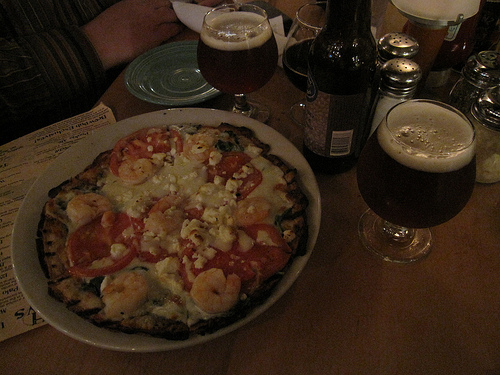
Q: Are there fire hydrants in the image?
A: No, there are no fire hydrants.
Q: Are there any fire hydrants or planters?
A: No, there are no fire hydrants or planters.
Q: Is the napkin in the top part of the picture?
A: Yes, the napkin is in the top of the image.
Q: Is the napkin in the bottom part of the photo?
A: No, the napkin is in the top of the image.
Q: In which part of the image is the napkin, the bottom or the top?
A: The napkin is in the top of the image.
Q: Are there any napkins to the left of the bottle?
A: Yes, there is a napkin to the left of the bottle.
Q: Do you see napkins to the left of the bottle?
A: Yes, there is a napkin to the left of the bottle.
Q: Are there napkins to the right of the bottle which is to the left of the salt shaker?
A: No, the napkin is to the left of the bottle.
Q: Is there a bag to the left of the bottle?
A: No, there is a napkin to the left of the bottle.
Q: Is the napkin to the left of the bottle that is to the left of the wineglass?
A: Yes, the napkin is to the left of the bottle.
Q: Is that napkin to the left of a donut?
A: No, the napkin is to the left of the bottle.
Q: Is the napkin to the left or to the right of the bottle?
A: The napkin is to the left of the bottle.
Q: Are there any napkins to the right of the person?
A: Yes, there is a napkin to the right of the person.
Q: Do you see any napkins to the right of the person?
A: Yes, there is a napkin to the right of the person.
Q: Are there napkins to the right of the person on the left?
A: Yes, there is a napkin to the right of the person.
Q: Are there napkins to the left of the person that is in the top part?
A: No, the napkin is to the right of the person.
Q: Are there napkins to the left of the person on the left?
A: No, the napkin is to the right of the person.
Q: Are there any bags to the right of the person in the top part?
A: No, there is a napkin to the right of the person.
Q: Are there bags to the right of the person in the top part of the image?
A: No, there is a napkin to the right of the person.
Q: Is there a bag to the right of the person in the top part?
A: No, there is a napkin to the right of the person.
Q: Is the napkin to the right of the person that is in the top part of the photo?
A: Yes, the napkin is to the right of the person.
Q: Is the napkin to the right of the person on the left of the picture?
A: Yes, the napkin is to the right of the person.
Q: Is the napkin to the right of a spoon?
A: No, the napkin is to the right of the person.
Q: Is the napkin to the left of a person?
A: No, the napkin is to the right of a person.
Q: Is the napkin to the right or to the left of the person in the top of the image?
A: The napkin is to the right of the person.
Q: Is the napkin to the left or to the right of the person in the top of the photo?
A: The napkin is to the right of the person.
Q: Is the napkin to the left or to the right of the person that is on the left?
A: The napkin is to the right of the person.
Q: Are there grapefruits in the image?
A: No, there are no grapefruits.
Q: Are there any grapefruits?
A: No, there are no grapefruits.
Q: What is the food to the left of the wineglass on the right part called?
A: The food is shrimp.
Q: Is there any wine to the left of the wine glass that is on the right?
A: No, there is shrimp to the left of the wine glass.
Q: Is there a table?
A: Yes, there is a table.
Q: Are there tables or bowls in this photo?
A: Yes, there is a table.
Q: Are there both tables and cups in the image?
A: No, there is a table but no cups.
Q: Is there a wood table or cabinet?
A: Yes, there is a wood table.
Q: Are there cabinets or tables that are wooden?
A: Yes, the table is wooden.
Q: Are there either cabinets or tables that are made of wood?
A: Yes, the table is made of wood.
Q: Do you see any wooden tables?
A: Yes, there is a wood table.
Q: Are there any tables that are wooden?
A: Yes, there is a table that is wooden.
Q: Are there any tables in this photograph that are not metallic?
A: Yes, there is a wooden table.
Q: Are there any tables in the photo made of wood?
A: Yes, there is a table that is made of wood.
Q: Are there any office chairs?
A: No, there are no office chairs.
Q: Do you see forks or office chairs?
A: No, there are no office chairs or forks.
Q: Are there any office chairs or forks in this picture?
A: No, there are no office chairs or forks.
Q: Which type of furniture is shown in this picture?
A: The furniture is a table.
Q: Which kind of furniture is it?
A: The piece of furniture is a table.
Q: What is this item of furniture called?
A: This is a table.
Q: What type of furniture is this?
A: This is a table.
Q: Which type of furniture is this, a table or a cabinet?
A: This is a table.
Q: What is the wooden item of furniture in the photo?
A: The piece of furniture is a table.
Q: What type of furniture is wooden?
A: The furniture is a table.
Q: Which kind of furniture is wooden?
A: The furniture is a table.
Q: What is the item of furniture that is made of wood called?
A: The piece of furniture is a table.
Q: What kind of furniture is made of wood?
A: The furniture is a table.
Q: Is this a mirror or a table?
A: This is a table.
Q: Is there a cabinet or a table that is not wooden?
A: No, there is a table but it is wooden.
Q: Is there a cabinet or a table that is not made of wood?
A: No, there is a table but it is made of wood.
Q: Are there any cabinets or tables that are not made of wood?
A: No, there is a table but it is made of wood.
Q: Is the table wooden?
A: Yes, the table is wooden.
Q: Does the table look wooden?
A: Yes, the table is wooden.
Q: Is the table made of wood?
A: Yes, the table is made of wood.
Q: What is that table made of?
A: The table is made of wood.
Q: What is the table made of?
A: The table is made of wood.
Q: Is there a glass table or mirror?
A: No, there is a table but it is wooden.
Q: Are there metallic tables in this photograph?
A: No, there is a table but it is wooden.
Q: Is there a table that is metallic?
A: No, there is a table but it is wooden.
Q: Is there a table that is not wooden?
A: No, there is a table but it is wooden.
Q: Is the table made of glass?
A: No, the table is made of wood.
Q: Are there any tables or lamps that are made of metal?
A: No, there is a table but it is made of wood.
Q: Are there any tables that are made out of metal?
A: No, there is a table but it is made of wood.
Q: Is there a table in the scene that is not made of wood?
A: No, there is a table but it is made of wood.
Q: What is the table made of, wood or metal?
A: The table is made of wood.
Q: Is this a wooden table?
A: Yes, this is a wooden table.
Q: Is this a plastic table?
A: No, this is a wooden table.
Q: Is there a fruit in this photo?
A: No, there are no fruits.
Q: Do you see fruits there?
A: No, there are no fruits.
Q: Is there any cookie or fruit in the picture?
A: No, there are no fruits or cookies.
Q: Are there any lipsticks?
A: No, there are no lipsticks.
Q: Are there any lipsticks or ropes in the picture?
A: No, there are no lipsticks or ropes.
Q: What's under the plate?
A: The paper is under the plate.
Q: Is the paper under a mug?
A: No, the paper is under the plate.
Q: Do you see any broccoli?
A: No, there is no broccoli.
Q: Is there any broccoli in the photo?
A: No, there is no broccoli.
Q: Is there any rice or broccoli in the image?
A: No, there are no broccoli or rice.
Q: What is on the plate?
A: The dinner is on the plate.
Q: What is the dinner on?
A: The dinner is on the plate.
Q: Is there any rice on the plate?
A: No, there is dinner on the plate.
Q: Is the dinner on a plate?
A: Yes, the dinner is on a plate.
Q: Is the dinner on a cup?
A: No, the dinner is on a plate.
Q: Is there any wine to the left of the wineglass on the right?
A: No, there is dinner to the left of the wineglass.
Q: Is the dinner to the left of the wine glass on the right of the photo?
A: Yes, the dinner is to the left of the wineglass.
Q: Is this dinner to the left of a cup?
A: No, the dinner is to the left of the wineglass.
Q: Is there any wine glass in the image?
A: Yes, there is a wine glass.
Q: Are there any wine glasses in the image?
A: Yes, there is a wine glass.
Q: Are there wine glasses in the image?
A: Yes, there is a wine glass.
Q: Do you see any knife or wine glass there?
A: Yes, there is a wine glass.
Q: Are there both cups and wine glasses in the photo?
A: No, there is a wine glass but no cups.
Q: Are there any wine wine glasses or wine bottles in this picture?
A: Yes, there is a wine wine glass.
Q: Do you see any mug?
A: No, there are no mugs.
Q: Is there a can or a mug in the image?
A: No, there are no mugs or cans.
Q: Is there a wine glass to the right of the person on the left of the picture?
A: Yes, there is a wine glass to the right of the person.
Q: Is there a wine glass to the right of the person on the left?
A: Yes, there is a wine glass to the right of the person.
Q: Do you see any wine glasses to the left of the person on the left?
A: No, the wine glass is to the right of the person.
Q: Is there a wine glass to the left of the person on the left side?
A: No, the wine glass is to the right of the person.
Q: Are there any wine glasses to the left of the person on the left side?
A: No, the wine glass is to the right of the person.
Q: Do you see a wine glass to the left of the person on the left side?
A: No, the wine glass is to the right of the person.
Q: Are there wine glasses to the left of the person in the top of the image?
A: No, the wine glass is to the right of the person.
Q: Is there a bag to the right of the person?
A: No, there is a wine glass to the right of the person.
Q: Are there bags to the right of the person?
A: No, there is a wine glass to the right of the person.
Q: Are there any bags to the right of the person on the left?
A: No, there is a wine glass to the right of the person.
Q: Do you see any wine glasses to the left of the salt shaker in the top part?
A: Yes, there is a wine glass to the left of the salt shaker.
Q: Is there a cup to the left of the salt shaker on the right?
A: No, there is a wine glass to the left of the salt shaker.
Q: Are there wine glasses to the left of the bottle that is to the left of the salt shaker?
A: Yes, there is a wine glass to the left of the bottle.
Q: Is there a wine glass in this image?
A: Yes, there is a wine glass.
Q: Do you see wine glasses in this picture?
A: Yes, there is a wine glass.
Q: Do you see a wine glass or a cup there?
A: Yes, there is a wine glass.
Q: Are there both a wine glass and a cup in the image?
A: No, there is a wine glass but no cups.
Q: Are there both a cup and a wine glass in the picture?
A: No, there is a wine glass but no cups.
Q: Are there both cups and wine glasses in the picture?
A: No, there is a wine glass but no cups.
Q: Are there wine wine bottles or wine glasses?
A: Yes, there is a wine wine glass.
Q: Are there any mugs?
A: No, there are no mugs.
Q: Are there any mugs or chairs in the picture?
A: No, there are no mugs or chairs.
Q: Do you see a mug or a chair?
A: No, there are no mugs or chairs.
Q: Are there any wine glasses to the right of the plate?
A: Yes, there is a wine glass to the right of the plate.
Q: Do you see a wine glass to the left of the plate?
A: No, the wine glass is to the right of the plate.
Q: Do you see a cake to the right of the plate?
A: No, there is a wine glass to the right of the plate.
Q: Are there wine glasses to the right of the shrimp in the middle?
A: Yes, there is a wine glass to the right of the shrimp.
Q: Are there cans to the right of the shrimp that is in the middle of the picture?
A: No, there is a wine glass to the right of the shrimp.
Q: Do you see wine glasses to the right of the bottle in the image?
A: Yes, there is a wine glass to the right of the bottle.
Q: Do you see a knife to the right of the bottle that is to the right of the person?
A: No, there is a wine glass to the right of the bottle.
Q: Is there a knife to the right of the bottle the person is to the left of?
A: No, there is a wine glass to the right of the bottle.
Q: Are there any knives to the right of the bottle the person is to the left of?
A: No, there is a wine glass to the right of the bottle.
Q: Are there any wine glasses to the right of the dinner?
A: Yes, there is a wine glass to the right of the dinner.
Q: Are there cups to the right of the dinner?
A: No, there is a wine glass to the right of the dinner.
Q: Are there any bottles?
A: Yes, there is a bottle.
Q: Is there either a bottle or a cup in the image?
A: Yes, there is a bottle.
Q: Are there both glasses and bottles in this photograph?
A: Yes, there are both a bottle and glasses.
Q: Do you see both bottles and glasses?
A: Yes, there are both a bottle and glasses.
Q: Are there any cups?
A: No, there are no cups.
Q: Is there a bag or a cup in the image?
A: No, there are no cups or bags.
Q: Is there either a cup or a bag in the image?
A: No, there are no cups or bags.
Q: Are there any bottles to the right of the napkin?
A: Yes, there is a bottle to the right of the napkin.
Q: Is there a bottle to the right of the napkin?
A: Yes, there is a bottle to the right of the napkin.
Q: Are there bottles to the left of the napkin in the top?
A: No, the bottle is to the right of the napkin.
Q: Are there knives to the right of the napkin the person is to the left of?
A: No, there is a bottle to the right of the napkin.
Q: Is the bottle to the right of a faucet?
A: No, the bottle is to the right of the napkin.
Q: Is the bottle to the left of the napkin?
A: No, the bottle is to the right of the napkin.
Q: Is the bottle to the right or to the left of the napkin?
A: The bottle is to the right of the napkin.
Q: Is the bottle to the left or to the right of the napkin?
A: The bottle is to the right of the napkin.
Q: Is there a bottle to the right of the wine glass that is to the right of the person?
A: Yes, there is a bottle to the right of the wine glass.